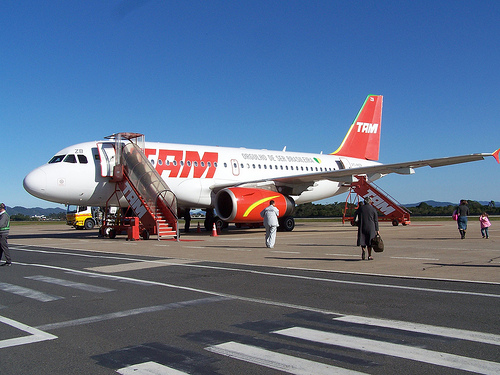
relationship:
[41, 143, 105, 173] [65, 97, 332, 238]
windows of plane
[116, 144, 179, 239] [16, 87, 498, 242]
orange stairs of plane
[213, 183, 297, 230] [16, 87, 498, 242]
booster on plane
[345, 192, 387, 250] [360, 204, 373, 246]
man wearing coat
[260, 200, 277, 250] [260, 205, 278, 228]
man wearing jacket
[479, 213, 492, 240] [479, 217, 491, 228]
girl wearing coat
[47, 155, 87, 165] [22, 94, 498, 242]
cockpit windows on airplane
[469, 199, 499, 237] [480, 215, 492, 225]
girl with coat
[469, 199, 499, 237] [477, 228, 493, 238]
girl with jeans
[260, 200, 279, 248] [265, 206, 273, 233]
man wearing track suit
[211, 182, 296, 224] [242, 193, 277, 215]
propellor with stripe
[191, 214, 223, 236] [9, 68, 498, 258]
cones underneath airplane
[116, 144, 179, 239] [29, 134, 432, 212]
orange stairs leading up to airplane